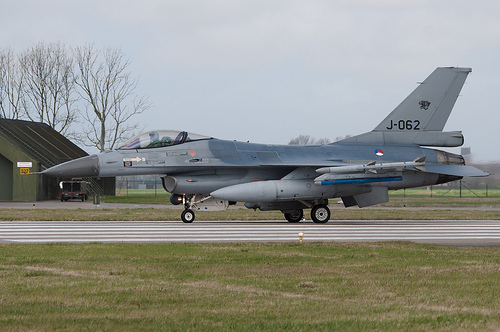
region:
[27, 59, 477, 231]
large grey military plane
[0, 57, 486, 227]
grey plane next to building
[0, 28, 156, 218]
green building in front of trees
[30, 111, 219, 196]
pointed nose and cockpit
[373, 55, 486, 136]
numbers and letters on tail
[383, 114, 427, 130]
black numbers and letter reads j-062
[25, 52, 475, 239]
plane with three wheels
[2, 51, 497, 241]
plane on white lined runway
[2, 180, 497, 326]
green grass around plane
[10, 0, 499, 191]
grey overcast sky with clouds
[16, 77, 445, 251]
This is a fighter jet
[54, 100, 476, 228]
The plane is grey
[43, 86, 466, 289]
The plane is on the runway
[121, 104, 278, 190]
The pilot is in the cockpit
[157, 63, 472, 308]
It is cloudy outside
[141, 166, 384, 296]
The plane has 3 wings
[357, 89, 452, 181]
This identifies the plane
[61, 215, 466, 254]
The runway is grey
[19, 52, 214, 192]
The trees are dead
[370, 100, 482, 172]
The writing is black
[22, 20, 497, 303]
A picture of a jet.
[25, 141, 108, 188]
The nose of a jet.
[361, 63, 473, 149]
The tail of a jet.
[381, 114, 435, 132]
The lettering J-062.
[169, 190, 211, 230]
The front wheels of a jet.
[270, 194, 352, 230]
The back wheels of a jet.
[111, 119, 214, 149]
The cockpit of a jet.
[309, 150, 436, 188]
A missile on a jet.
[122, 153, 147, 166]
A white arrow pointing right.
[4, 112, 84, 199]
A building to the left.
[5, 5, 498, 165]
hazy grey sky with clouds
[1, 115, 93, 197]
dark green building with yellow sign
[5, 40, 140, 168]
tall brown leafless trees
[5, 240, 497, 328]
green and brown grass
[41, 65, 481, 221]
grey jet plane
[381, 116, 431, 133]
black lettering on plane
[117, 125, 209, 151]
clear cockpit of plane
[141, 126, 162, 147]
person sitting in plane cockpit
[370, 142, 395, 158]
tricolored circle on plane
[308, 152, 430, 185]
missile shaped objects on plane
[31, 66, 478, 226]
a fighter plane is on the runway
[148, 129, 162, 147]
the pilot of the fighter plane is in the cockpit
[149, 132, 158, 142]
the pilot is wearing a helmet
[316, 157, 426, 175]
the plane has missiles attached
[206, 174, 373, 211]
a large missile is under the wing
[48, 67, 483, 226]
the fighter plane is grey in color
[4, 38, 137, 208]
bare trees are in the background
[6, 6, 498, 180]
the sky is overcast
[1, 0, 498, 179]
the sky is blue in color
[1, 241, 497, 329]
there are brown patches of grass on the ground